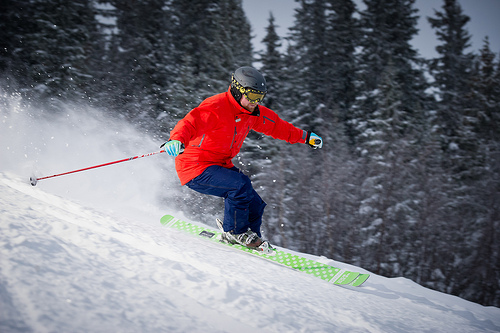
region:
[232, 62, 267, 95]
A black helmet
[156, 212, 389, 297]
A green ski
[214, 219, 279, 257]
The white boot of the ski.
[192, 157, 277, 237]
A blue pair of pants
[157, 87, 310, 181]
A red jacket.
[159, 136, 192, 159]
The hand holds the pole handle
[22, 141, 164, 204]
The pole is red.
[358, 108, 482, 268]
Snow covered trees in the forrest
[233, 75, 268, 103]
A yellow pair of googles.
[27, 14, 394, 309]
A man skies down the mountain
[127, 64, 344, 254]
skier on snowy slope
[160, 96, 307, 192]
red jacket on skier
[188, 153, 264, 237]
blue pants on skier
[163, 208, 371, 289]
green and white ski on snow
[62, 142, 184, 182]
red pole in hand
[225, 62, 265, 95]
gray helmet on head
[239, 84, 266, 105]
goggles on man's face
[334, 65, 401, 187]
snow on pine trees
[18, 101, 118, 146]
snow spraying in the air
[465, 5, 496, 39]
blue of daytime sky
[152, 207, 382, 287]
green and white ski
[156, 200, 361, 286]
checkered ski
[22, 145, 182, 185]
red ski pole with white top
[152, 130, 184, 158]
man holds ski pole with right hand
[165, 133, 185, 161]
man wearing blue globes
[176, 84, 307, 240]
man in red jacket and blue jeans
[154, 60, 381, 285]
man tilted sideways on ski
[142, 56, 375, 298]
man skiing downhill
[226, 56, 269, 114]
gray helmet with yellow and black goggles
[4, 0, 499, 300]
snow-capped trees behind snow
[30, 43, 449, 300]
A person downhill skiing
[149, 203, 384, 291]
A green and white ski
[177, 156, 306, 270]
A person wearing blue snow pants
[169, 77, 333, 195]
A person wearing a red jacket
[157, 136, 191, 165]
Blue and yellow ski gloves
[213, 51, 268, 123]
A person wearing a helmet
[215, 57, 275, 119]
A person wearing goggles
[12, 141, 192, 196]
A downhill ski pole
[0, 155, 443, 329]
Snow on a mountain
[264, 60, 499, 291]
Snow covered trees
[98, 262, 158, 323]
white snow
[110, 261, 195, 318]
white snow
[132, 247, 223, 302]
white snow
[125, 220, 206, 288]
white snow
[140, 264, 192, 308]
white snow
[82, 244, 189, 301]
white snow